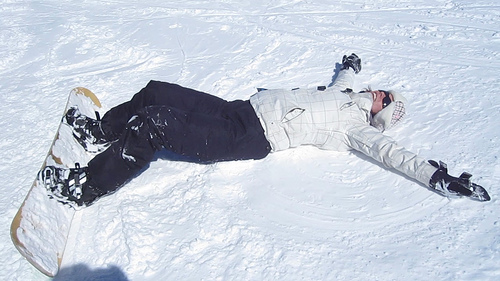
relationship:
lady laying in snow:
[36, 52, 492, 212] [6, 4, 496, 280]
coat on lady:
[243, 58, 448, 185] [36, 52, 492, 212]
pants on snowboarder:
[61, 80, 268, 207] [48, 14, 484, 223]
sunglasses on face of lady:
[381, 85, 391, 112] [36, 52, 492, 212]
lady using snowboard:
[36, 52, 492, 212] [17, 80, 104, 280]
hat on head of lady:
[377, 84, 409, 134] [36, 52, 492, 212]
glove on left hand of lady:
[433, 164, 491, 202] [36, 52, 492, 212]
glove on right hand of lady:
[427, 159, 489, 202] [36, 52, 492, 212]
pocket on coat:
[284, 98, 304, 125] [243, 58, 448, 185]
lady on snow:
[36, 52, 492, 212] [6, 4, 496, 280]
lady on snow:
[46, 56, 491, 194] [6, 4, 496, 280]